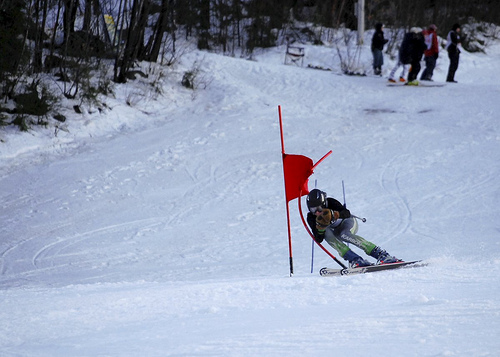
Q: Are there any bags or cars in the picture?
A: No, there are no bags or cars.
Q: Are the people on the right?
A: Yes, the people are on the right of the image.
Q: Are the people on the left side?
A: No, the people are on the right of the image.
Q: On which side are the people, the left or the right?
A: The people are on the right of the image.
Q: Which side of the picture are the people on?
A: The people are on the right of the image.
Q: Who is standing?
A: The people are standing.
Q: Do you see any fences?
A: No, there are no fences.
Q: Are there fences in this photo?
A: No, there are no fences.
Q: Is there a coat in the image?
A: Yes, there is a coat.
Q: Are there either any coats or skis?
A: Yes, there is a coat.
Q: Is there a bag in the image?
A: No, there are no bags.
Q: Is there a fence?
A: No, there are no fences.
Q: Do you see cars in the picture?
A: No, there are no cars.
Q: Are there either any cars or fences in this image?
A: No, there are no cars or fences.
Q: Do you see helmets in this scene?
A: Yes, there is a helmet.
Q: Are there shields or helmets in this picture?
A: Yes, there is a helmet.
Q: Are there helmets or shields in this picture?
A: Yes, there is a helmet.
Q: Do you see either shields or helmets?
A: Yes, there is a helmet.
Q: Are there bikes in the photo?
A: No, there are no bikes.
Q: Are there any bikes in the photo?
A: No, there are no bikes.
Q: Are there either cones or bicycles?
A: No, there are no bicycles or cones.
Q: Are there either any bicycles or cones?
A: No, there are no bicycles or cones.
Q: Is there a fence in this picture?
A: No, there are no fences.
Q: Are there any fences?
A: No, there are no fences.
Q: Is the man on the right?
A: Yes, the man is on the right of the image.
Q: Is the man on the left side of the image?
A: No, the man is on the right of the image.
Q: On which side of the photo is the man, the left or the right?
A: The man is on the right of the image.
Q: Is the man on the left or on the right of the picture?
A: The man is on the right of the image.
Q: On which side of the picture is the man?
A: The man is on the right of the image.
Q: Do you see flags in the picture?
A: Yes, there is a flag.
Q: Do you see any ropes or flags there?
A: Yes, there is a flag.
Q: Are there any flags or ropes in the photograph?
A: Yes, there is a flag.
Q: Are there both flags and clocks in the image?
A: No, there is a flag but no clocks.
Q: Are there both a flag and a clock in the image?
A: No, there is a flag but no clocks.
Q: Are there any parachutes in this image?
A: No, there are no parachutes.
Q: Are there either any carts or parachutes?
A: No, there are no parachutes or carts.